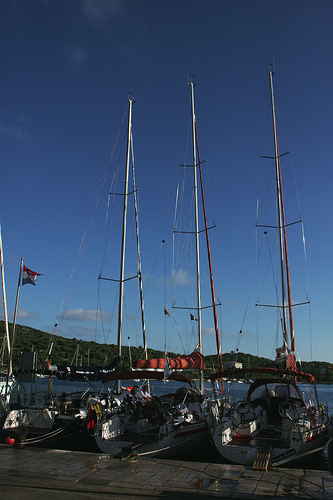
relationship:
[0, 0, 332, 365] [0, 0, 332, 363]
clouds in sky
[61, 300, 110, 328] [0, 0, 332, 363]
clouds in sky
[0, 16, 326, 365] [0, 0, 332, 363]
cloud in sky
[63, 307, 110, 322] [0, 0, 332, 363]
cloud in sky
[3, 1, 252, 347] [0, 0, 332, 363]
clouds in sky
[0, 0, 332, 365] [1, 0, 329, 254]
clouds in sky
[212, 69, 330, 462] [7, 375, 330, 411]
sailboat on water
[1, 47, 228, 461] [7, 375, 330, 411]
sailboat on water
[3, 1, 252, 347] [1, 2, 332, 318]
clouds on sky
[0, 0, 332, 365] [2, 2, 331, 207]
clouds in sky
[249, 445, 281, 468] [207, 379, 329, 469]
ramp coming from boat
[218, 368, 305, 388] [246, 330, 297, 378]
sail on mast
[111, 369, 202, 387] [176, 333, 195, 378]
sail on mast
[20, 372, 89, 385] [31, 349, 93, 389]
sail on mast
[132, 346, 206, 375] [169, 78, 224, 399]
sail on mast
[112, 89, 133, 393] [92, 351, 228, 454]
mast on boat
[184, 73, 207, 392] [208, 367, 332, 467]
mast on boat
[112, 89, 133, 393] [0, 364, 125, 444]
mast on boat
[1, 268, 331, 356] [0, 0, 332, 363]
clouds in sky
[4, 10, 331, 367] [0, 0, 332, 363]
area of sky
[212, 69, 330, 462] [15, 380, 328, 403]
sailboat on water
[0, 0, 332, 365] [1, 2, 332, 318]
clouds in sky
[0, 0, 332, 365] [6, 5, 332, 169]
clouds in sky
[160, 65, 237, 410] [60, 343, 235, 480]
mast on boat